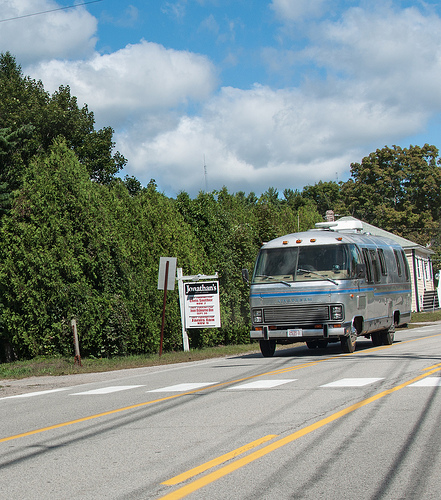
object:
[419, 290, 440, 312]
stairs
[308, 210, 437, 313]
house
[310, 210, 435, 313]
building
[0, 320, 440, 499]
street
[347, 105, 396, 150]
wall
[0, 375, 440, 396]
crosswalk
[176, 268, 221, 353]
white post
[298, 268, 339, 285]
wiper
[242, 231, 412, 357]
vehicle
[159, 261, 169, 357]
post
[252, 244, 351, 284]
windshield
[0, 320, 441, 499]
road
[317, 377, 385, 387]
box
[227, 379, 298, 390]
box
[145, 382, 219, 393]
box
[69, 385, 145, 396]
box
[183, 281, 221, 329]
sign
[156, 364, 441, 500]
line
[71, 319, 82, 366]
pole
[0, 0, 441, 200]
clouds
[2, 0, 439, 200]
sky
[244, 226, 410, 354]
camper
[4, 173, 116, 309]
foliage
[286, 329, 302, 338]
license plate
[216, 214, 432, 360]
motor home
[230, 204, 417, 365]
van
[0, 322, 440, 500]
driveway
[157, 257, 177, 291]
sign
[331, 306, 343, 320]
headlights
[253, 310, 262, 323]
headlights